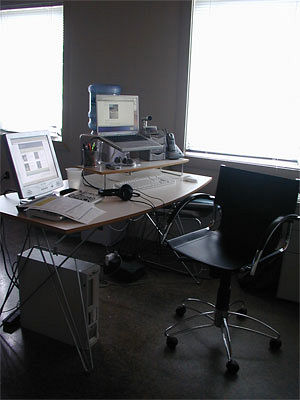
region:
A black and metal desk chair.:
[160, 163, 299, 374]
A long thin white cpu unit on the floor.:
[16, 245, 101, 347]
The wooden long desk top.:
[1, 167, 212, 233]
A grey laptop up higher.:
[94, 92, 163, 151]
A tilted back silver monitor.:
[2, 132, 64, 200]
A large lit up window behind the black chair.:
[184, 0, 298, 171]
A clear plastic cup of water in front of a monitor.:
[65, 166, 83, 189]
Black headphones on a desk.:
[98, 183, 134, 200]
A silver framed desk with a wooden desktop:
[6, 132, 225, 369]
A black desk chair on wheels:
[142, 164, 292, 383]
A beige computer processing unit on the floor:
[10, 249, 102, 352]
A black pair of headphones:
[93, 185, 156, 214]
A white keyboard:
[110, 169, 180, 195]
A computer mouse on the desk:
[179, 172, 199, 185]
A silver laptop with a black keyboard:
[91, 88, 141, 136]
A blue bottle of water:
[85, 80, 121, 134]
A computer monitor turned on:
[5, 128, 72, 200]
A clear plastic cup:
[64, 166, 84, 190]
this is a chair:
[163, 173, 298, 359]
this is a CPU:
[17, 254, 100, 335]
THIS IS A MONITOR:
[10, 130, 61, 187]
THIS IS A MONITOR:
[100, 95, 139, 133]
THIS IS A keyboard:
[110, 133, 159, 148]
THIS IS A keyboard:
[37, 185, 98, 215]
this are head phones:
[98, 182, 140, 199]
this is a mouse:
[177, 168, 195, 180]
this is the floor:
[114, 307, 128, 337]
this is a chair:
[188, 171, 292, 381]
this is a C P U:
[19, 252, 94, 336]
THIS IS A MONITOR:
[7, 127, 60, 192]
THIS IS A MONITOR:
[96, 93, 140, 131]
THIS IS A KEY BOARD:
[38, 183, 87, 215]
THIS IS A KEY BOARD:
[109, 133, 158, 146]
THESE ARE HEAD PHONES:
[102, 174, 144, 205]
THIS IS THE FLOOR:
[113, 282, 125, 346]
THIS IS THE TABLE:
[103, 200, 118, 217]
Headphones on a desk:
[97, 182, 136, 203]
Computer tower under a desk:
[16, 248, 103, 350]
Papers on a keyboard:
[29, 192, 105, 226]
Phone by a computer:
[160, 126, 185, 165]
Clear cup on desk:
[65, 164, 86, 189]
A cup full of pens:
[76, 138, 100, 169]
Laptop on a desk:
[93, 92, 167, 157]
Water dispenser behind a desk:
[84, 83, 123, 136]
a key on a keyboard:
[128, 178, 134, 183]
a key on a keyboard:
[134, 177, 140, 183]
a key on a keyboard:
[144, 175, 147, 181]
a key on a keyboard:
[149, 179, 153, 185]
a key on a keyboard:
[142, 182, 144, 186]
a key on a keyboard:
[148, 184, 150, 185]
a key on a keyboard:
[154, 182, 155, 183]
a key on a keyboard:
[167, 177, 171, 182]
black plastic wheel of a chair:
[222, 356, 245, 376]